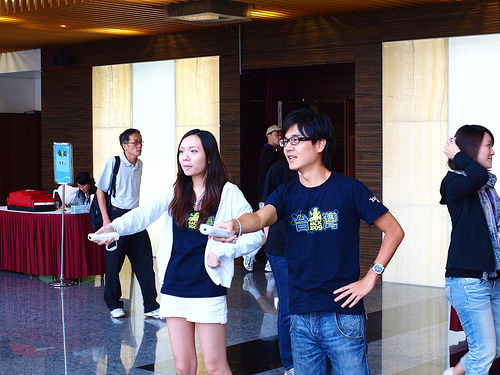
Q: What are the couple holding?
A: Wii controllers.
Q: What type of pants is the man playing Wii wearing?
A: Blue jeans.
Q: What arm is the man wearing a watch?
A: Left.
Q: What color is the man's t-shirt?
A: Blue.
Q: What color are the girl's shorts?
A: White.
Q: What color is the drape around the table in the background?
A: Red.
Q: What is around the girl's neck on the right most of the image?
A: A scarf.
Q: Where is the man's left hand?
A: On his hip.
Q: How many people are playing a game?
A: Two.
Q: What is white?
A: Game controllers.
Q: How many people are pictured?
A: Five.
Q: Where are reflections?
A: On the floor.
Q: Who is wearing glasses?
A: Guy on right.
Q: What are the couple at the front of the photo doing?
A: Playing Wii.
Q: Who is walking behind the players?
A: A man and a woman.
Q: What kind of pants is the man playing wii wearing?
A: Blue jeans.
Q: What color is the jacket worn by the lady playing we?
A: White.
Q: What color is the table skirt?
A: Red.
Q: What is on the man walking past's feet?
A: Sneakers.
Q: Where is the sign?
A: In front of the table.